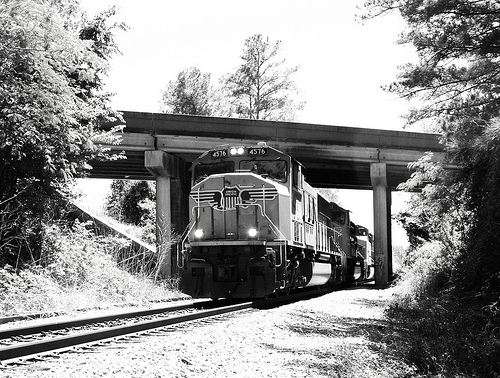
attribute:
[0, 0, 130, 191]
leaves — small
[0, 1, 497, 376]
scene — day time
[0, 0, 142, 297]
tree — on the left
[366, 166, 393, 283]
column — concrete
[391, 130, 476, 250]
leaves — small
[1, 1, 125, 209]
leaves — small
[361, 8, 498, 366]
tree — on the right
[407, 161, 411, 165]
leaf — small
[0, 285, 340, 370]
track — train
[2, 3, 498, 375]
outside — scene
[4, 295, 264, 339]
track — train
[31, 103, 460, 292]
bridge — concrete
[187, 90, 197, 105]
leaves — small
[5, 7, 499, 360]
clear day — bright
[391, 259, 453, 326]
leaves — small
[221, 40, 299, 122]
tree — small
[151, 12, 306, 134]
trees — in the background